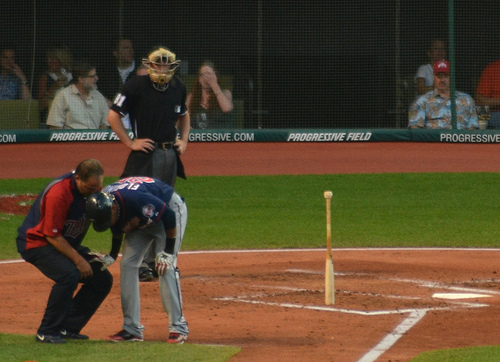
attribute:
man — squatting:
[19, 153, 116, 338]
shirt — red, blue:
[22, 176, 87, 243]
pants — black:
[19, 241, 105, 332]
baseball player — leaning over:
[88, 182, 188, 254]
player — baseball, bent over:
[78, 145, 188, 249]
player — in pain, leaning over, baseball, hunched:
[83, 174, 190, 345]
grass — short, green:
[214, 189, 316, 233]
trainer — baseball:
[13, 157, 115, 346]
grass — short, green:
[5, 340, 183, 360]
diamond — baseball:
[240, 244, 499, 328]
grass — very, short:
[346, 181, 431, 231]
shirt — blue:
[84, 174, 183, 235]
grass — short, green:
[360, 183, 436, 233]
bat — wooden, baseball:
[293, 177, 361, 313]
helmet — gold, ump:
[138, 45, 188, 87]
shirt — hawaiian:
[414, 90, 484, 135]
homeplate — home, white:
[417, 282, 497, 314]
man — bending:
[15, 163, 115, 342]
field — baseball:
[2, 147, 496, 359]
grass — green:
[177, 173, 495, 246]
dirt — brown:
[175, 252, 492, 352]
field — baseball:
[1, 177, 497, 359]